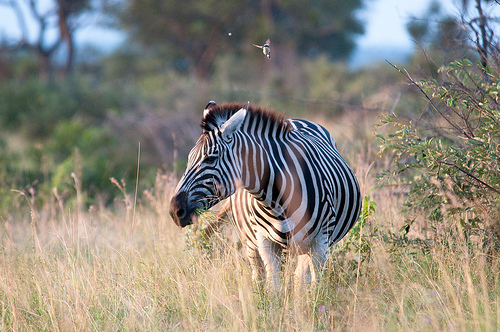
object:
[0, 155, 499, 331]
grass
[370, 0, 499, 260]
bush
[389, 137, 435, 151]
leaves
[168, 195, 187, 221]
nose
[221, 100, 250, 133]
ear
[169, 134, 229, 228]
face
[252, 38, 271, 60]
bird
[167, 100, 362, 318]
zebra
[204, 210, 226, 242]
tail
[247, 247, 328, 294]
leg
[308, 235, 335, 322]
leg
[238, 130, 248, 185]
stripe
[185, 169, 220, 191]
stripe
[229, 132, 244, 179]
stripe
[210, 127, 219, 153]
stripe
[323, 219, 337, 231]
stripe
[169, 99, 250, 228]
head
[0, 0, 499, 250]
tree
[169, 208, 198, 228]
mouth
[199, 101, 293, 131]
hair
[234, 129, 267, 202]
zebra's neck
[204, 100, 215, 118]
ear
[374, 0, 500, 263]
branch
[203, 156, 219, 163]
eye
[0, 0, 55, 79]
leafless trees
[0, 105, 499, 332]
field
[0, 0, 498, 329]
background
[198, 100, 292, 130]
mane